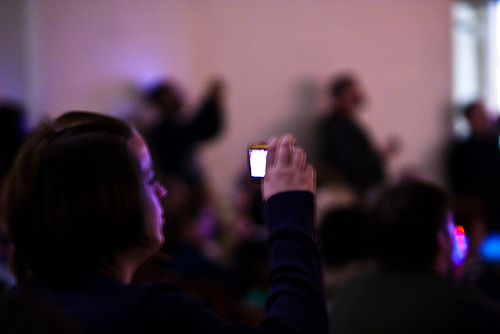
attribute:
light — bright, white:
[252, 153, 264, 174]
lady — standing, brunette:
[1, 105, 326, 332]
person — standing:
[314, 71, 393, 185]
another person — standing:
[145, 71, 227, 189]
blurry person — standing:
[445, 100, 497, 192]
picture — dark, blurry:
[2, 2, 496, 333]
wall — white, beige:
[8, 3, 452, 189]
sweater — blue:
[3, 188, 329, 334]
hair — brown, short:
[0, 111, 139, 282]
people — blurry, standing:
[11, 66, 495, 320]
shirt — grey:
[331, 273, 496, 332]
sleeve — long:
[252, 191, 331, 332]